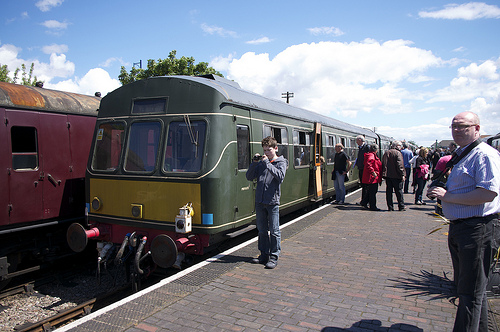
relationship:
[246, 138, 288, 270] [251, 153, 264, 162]
boy has a phone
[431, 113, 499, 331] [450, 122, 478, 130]
man wearing glasses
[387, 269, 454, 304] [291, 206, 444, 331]
shadow on platform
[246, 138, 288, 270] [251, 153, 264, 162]
boy has a camera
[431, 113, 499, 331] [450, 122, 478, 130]
man has glasses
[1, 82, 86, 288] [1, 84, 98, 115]
train has a rusty roof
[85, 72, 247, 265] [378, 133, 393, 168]
train engine pulling train cars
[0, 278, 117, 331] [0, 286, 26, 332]
train tracks have gravel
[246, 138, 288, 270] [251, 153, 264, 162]
boy taking a picture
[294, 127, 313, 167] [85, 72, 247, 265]
passenger windows on train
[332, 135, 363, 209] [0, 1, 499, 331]
passengers at train station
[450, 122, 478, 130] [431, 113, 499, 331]
glasses on man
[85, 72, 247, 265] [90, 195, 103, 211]
train has lights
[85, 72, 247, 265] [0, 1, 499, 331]
train at station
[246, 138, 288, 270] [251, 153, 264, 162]
child with a camera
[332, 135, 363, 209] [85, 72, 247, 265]
passengers boarding train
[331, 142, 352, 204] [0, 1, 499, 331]
passengers at train station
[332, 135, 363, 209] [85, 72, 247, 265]
passengers of train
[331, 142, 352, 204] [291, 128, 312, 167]
passenger train windows